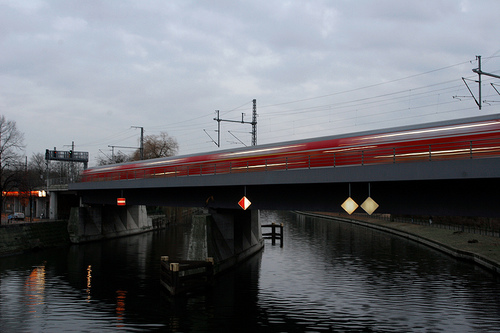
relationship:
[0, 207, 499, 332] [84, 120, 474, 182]
canal under bridge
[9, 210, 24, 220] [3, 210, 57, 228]
vehicle parked in lot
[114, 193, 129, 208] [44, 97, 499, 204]
sign mounted on bridge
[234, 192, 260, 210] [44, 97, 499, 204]
sign mounted on bridge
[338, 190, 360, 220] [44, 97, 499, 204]
sign mounted on bridge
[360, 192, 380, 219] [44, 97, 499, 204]
sign mounted on bridge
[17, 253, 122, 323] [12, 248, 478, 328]
lights reflecting on water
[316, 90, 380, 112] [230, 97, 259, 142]
lines between poles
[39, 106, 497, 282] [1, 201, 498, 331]
bridge over water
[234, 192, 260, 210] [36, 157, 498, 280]
sign hanging from bridge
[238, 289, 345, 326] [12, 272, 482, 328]
ripples in water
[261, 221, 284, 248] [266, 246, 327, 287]
fencing in water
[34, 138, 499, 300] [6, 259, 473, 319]
bridge over water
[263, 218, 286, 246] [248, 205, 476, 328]
fencing in water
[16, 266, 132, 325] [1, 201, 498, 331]
reflections on water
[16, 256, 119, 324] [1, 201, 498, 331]
reflections on water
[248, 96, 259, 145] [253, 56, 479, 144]
pole for electrical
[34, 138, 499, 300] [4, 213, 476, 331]
bridge over canal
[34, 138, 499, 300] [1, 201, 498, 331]
bridge over water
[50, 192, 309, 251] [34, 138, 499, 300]
supports under bridge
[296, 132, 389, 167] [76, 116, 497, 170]
blur from train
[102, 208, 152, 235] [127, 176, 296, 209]
pillar on bridge